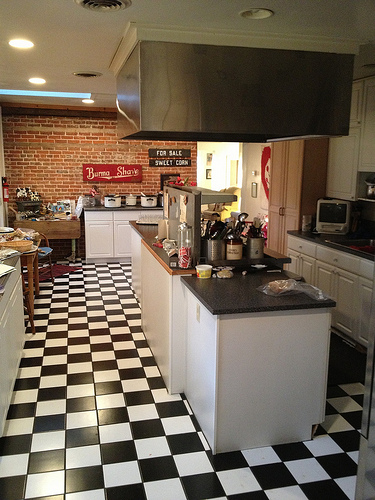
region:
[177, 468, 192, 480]
the tile is black and white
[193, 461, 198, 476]
the tile is black and white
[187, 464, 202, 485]
the tile is black and white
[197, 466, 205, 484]
the tile is black and white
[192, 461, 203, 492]
the tile is black and white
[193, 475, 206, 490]
the tile is black and white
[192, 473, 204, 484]
the tile is black and white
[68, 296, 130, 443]
this is the floor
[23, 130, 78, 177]
this is the wall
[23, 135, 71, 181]
the wall is made of bricks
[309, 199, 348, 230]
this is a television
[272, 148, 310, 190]
this is a cupboard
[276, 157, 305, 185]
the cupboard is brown in color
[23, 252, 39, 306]
this is a table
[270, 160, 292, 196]
the cupboard is wooden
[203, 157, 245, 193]
this is the door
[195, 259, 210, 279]
this is a container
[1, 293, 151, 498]
a black and white checkered floor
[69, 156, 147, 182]
a red sign on a brick wall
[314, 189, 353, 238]
a white tv on the counter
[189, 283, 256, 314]
the counter tops are a dark color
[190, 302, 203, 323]
an electric outlet on the island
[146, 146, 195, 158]
a for sale sign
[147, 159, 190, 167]
a sweet corn sign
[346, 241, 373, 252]
a red dish cloth on the sink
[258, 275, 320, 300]
a plastic bag on the counter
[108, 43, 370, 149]
a large kitchen vent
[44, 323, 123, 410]
black and white tiles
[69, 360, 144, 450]
black and white tiles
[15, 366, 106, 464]
black and white tiles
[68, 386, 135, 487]
black and white tiles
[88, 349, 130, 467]
black and white tiles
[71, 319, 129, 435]
Checkered tile floor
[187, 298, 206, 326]
Electrical receptacle built in to counter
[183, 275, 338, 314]
Granite countertop on cabinet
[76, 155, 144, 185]
Sign hung on brick wall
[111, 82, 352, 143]
Exhaust fan duct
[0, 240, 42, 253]
Wicker basket on tabletop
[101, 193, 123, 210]
Pot sitting on the counter top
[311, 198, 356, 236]
Small TV on countertop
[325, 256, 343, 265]
Handle for cabinet drawer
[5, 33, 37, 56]
Spotlight built in to ceiling